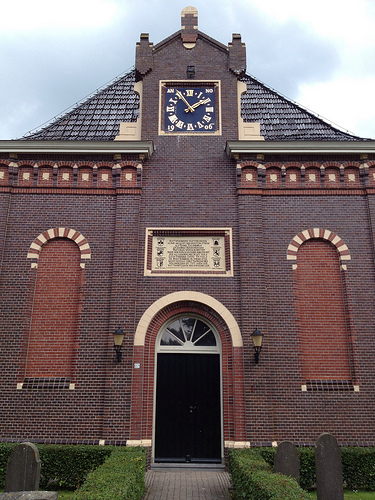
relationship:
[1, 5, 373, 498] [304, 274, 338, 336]
building made of bricks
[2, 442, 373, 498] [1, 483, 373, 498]
hedges in yard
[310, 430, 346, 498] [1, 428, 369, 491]
tombstone in yard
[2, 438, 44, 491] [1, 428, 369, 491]
tombstone in yard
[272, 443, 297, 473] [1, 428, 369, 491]
tombstone in yard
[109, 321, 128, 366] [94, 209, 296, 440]
light attached to wall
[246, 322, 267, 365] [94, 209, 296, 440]
light attached to wall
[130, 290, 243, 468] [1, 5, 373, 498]
entrance into building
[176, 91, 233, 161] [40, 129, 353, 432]
floor in front of building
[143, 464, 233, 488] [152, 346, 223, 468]
sidewalk leading to door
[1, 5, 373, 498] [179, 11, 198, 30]
building with cross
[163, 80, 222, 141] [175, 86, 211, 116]
clock showing time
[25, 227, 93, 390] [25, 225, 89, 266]
window with top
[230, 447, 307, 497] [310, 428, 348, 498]
shurbs beside tombstones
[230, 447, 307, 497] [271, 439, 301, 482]
shurbs beside tombstones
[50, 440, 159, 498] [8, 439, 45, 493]
shurbs behind tombstones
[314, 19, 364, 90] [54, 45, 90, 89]
clouds in sky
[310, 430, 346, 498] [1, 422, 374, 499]
tombstone in a cemetary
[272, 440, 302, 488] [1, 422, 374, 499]
tombstone in a cemetary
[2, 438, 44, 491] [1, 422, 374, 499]
tombstone in a cemetary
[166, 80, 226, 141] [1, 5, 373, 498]
clock on building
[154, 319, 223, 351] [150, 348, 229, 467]
window above door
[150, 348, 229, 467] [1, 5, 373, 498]
door to building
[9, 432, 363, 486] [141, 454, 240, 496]
hedge row along walkway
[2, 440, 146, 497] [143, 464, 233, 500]
hedge along sidewalk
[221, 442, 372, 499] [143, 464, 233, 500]
hedges along sidewalk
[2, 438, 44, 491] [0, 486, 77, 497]
tombstone in cemetary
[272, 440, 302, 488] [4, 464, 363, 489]
tombstone in cemetery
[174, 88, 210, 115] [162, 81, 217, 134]
time on clock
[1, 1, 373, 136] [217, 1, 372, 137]
sky with cloud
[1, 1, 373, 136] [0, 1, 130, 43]
sky with cloud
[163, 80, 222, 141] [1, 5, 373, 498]
clock on building